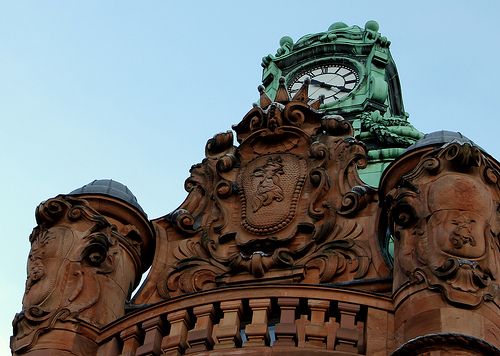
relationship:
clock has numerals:
[283, 55, 366, 105] [275, 49, 372, 108]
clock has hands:
[252, 16, 424, 163] [288, 61, 359, 108]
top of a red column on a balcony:
[64, 174, 128, 240] [34, 106, 235, 185]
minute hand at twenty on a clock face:
[304, 82, 354, 96] [300, 100, 363, 121]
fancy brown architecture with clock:
[43, 180, 495, 281] [243, 103, 307, 106]